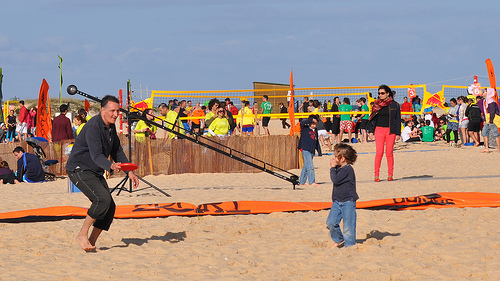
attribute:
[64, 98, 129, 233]
man — barefoot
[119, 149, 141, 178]
frisbee — red, round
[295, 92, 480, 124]
people — standing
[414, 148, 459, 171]
beach — sandy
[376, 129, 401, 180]
pants — red, tight, pink, long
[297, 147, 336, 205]
jeans — blue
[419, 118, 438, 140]
shirt — green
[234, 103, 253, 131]
shirt — yellow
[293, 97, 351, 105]
net — orange, yellow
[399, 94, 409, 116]
top — red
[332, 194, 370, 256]
jeans — blue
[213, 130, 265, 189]
fence — wooden, short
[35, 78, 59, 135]
banner — orange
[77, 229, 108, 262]
feet — bare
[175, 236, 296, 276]
sand — tan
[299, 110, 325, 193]
woman — walking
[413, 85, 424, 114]
trim — yellow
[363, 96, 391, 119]
scarf — red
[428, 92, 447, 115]
bull — red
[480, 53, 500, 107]
flag — orange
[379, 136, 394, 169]
jeans — skinny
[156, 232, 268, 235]
ground — sand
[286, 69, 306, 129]
sign — orange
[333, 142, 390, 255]
kid — standing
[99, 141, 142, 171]
disc — red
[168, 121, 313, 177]
equipment — black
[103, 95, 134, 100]
hair — black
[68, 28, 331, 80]
sky — blue, clear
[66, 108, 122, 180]
shirt — black